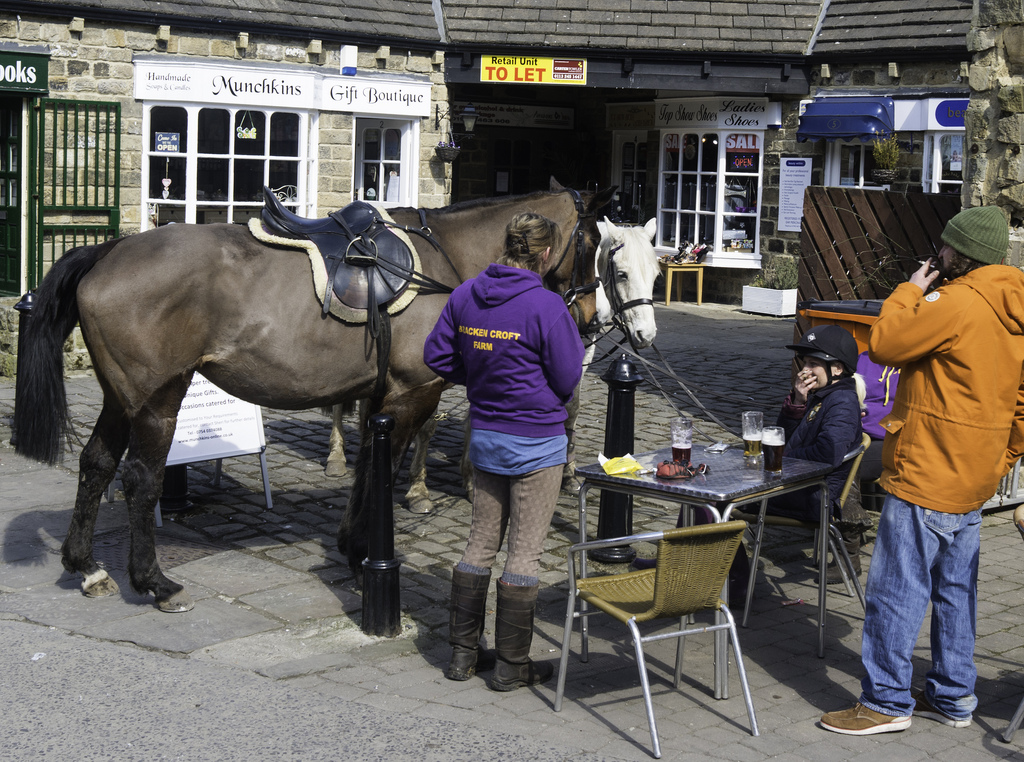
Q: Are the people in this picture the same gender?
A: No, they are both male and female.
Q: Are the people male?
A: No, they are both male and female.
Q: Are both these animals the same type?
A: Yes, all the animals are horses.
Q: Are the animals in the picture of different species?
A: No, all the animals are horses.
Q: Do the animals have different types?
A: No, all the animals are horses.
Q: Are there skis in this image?
A: No, there are no skis.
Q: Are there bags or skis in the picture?
A: No, there are no skis or bags.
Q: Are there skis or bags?
A: No, there are no skis or bags.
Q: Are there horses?
A: Yes, there is a horse.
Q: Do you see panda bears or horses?
A: Yes, there is a horse.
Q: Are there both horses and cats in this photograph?
A: No, there is a horse but no cats.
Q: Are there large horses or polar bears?
A: Yes, there is a large horse.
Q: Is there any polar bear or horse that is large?
A: Yes, the horse is large.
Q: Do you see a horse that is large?
A: Yes, there is a large horse.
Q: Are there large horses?
A: Yes, there is a large horse.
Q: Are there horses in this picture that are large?
A: Yes, there is a horse that is large.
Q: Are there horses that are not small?
A: Yes, there is a large horse.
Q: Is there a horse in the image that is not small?
A: Yes, there is a large horse.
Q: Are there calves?
A: No, there are no calves.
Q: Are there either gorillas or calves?
A: No, there are no calves or gorillas.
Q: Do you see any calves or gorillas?
A: No, there are no calves or gorillas.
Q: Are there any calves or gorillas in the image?
A: No, there are no calves or gorillas.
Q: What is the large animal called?
A: The animal is a horse.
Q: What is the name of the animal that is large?
A: The animal is a horse.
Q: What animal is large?
A: The animal is a horse.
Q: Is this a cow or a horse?
A: This is a horse.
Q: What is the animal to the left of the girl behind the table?
A: The animal is a horse.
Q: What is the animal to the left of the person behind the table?
A: The animal is a horse.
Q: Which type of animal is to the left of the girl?
A: The animal is a horse.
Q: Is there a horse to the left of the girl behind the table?
A: Yes, there is a horse to the left of the girl.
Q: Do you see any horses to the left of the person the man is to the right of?
A: Yes, there is a horse to the left of the girl.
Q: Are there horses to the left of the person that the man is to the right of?
A: Yes, there is a horse to the left of the girl.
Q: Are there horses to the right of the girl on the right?
A: No, the horse is to the left of the girl.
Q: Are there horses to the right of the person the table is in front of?
A: No, the horse is to the left of the girl.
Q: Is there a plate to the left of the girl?
A: No, there is a horse to the left of the girl.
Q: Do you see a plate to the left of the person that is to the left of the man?
A: No, there is a horse to the left of the girl.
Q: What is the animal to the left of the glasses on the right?
A: The animal is a horse.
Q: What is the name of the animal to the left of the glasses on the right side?
A: The animal is a horse.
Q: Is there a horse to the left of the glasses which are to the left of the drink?
A: Yes, there is a horse to the left of the glasses.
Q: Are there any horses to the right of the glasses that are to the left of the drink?
A: No, the horse is to the left of the glasses.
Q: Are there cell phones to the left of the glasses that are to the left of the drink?
A: No, there is a horse to the left of the glasses.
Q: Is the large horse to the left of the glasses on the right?
A: Yes, the horse is to the left of the glasses.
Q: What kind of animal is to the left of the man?
A: The animal is a horse.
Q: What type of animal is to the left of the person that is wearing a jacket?
A: The animal is a horse.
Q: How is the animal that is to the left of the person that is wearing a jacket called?
A: The animal is a horse.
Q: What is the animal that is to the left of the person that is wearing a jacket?
A: The animal is a horse.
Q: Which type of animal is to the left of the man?
A: The animal is a horse.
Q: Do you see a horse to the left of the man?
A: Yes, there is a horse to the left of the man.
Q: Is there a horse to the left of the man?
A: Yes, there is a horse to the left of the man.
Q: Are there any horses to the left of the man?
A: Yes, there is a horse to the left of the man.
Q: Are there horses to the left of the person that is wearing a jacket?
A: Yes, there is a horse to the left of the man.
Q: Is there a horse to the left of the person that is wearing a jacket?
A: Yes, there is a horse to the left of the man.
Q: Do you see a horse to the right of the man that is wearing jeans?
A: No, the horse is to the left of the man.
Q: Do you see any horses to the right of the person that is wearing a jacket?
A: No, the horse is to the left of the man.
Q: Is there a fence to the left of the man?
A: No, there is a horse to the left of the man.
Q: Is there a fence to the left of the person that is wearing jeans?
A: No, there is a horse to the left of the man.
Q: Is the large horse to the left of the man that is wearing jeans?
A: Yes, the horse is to the left of the man.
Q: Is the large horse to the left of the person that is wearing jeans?
A: Yes, the horse is to the left of the man.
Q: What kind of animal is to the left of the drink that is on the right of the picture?
A: The animal is a horse.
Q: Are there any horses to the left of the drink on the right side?
A: Yes, there is a horse to the left of the drink.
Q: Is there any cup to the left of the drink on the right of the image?
A: No, there is a horse to the left of the drink.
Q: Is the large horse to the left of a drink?
A: Yes, the horse is to the left of a drink.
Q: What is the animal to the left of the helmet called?
A: The animal is a horse.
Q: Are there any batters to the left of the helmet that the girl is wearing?
A: No, there is a horse to the left of the helmet.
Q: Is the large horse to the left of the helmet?
A: Yes, the horse is to the left of the helmet.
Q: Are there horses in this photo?
A: Yes, there is a horse.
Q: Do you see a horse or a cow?
A: Yes, there is a horse.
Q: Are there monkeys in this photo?
A: No, there are no monkeys.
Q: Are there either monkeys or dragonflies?
A: No, there are no monkeys or dragonflies.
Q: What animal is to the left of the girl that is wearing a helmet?
A: The animal is a horse.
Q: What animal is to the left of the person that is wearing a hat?
A: The animal is a horse.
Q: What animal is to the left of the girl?
A: The animal is a horse.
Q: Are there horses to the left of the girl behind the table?
A: Yes, there is a horse to the left of the girl.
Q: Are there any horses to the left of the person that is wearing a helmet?
A: Yes, there is a horse to the left of the girl.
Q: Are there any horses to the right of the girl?
A: No, the horse is to the left of the girl.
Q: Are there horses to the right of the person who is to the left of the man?
A: No, the horse is to the left of the girl.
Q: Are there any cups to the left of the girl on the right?
A: No, there is a horse to the left of the girl.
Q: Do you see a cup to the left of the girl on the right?
A: No, there is a horse to the left of the girl.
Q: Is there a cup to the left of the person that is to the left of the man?
A: No, there is a horse to the left of the girl.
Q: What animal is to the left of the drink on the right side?
A: The animal is a horse.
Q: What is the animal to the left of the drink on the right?
A: The animal is a horse.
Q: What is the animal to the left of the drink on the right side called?
A: The animal is a horse.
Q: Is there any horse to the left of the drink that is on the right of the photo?
A: Yes, there is a horse to the left of the drink.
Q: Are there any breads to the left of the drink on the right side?
A: No, there is a horse to the left of the drink.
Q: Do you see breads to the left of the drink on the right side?
A: No, there is a horse to the left of the drink.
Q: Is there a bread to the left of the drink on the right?
A: No, there is a horse to the left of the drink.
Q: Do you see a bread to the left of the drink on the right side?
A: No, there is a horse to the left of the drink.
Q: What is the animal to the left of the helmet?
A: The animal is a horse.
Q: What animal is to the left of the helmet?
A: The animal is a horse.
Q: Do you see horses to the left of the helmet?
A: Yes, there is a horse to the left of the helmet.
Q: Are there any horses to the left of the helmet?
A: Yes, there is a horse to the left of the helmet.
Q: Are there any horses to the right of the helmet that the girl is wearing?
A: No, the horse is to the left of the helmet.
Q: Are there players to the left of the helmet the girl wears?
A: No, there is a horse to the left of the helmet.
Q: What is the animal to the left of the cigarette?
A: The animal is a horse.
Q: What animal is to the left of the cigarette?
A: The animal is a horse.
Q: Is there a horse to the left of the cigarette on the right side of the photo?
A: Yes, there is a horse to the left of the cigarette.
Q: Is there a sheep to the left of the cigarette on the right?
A: No, there is a horse to the left of the cigarette.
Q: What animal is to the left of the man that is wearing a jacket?
A: The animal is a horse.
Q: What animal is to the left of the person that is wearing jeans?
A: The animal is a horse.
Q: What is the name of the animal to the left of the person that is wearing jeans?
A: The animal is a horse.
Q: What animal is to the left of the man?
A: The animal is a horse.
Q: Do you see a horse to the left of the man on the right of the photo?
A: Yes, there is a horse to the left of the man.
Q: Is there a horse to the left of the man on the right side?
A: Yes, there is a horse to the left of the man.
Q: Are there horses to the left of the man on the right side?
A: Yes, there is a horse to the left of the man.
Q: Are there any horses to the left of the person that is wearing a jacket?
A: Yes, there is a horse to the left of the man.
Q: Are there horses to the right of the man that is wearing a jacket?
A: No, the horse is to the left of the man.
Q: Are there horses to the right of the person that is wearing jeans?
A: No, the horse is to the left of the man.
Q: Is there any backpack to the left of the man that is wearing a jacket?
A: No, there is a horse to the left of the man.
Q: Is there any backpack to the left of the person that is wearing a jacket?
A: No, there is a horse to the left of the man.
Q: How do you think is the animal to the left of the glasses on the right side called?
A: The animal is a horse.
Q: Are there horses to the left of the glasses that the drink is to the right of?
A: Yes, there is a horse to the left of the glasses.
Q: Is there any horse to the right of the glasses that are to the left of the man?
A: No, the horse is to the left of the glasses.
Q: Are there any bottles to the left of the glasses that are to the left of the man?
A: No, there is a horse to the left of the glasses.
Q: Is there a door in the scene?
A: Yes, there is a door.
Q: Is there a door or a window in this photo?
A: Yes, there is a door.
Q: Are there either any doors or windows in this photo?
A: Yes, there is a door.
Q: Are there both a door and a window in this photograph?
A: Yes, there are both a door and a window.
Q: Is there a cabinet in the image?
A: No, there are no cabinets.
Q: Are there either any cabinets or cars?
A: No, there are no cabinets or cars.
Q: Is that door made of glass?
A: No, the door is made of iron.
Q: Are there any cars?
A: No, there are no cars.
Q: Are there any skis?
A: No, there are no skis.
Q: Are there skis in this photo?
A: No, there are no skis.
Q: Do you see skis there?
A: No, there are no skis.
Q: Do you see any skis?
A: No, there are no skis.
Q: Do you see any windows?
A: Yes, there is a window.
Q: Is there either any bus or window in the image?
A: Yes, there is a window.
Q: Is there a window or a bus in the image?
A: Yes, there is a window.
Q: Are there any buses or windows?
A: Yes, there is a window.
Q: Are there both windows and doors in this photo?
A: Yes, there are both a window and a door.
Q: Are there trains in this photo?
A: No, there are no trains.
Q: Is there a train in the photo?
A: No, there are no trains.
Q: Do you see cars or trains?
A: No, there are no trains or cars.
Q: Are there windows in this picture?
A: Yes, there is a window.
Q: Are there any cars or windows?
A: Yes, there is a window.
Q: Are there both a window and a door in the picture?
A: Yes, there are both a window and a door.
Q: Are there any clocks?
A: No, there are no clocks.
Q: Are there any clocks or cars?
A: No, there are no clocks or cars.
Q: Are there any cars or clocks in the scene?
A: No, there are no clocks or cars.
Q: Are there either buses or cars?
A: No, there are no cars or buses.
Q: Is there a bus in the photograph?
A: No, there are no buses.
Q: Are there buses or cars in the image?
A: No, there are no buses or cars.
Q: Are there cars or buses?
A: No, there are no buses or cars.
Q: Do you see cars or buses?
A: No, there are no buses or cars.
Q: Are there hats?
A: Yes, there is a hat.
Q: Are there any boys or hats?
A: Yes, there is a hat.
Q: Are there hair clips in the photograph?
A: No, there are no hair clips.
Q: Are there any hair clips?
A: No, there are no hair clips.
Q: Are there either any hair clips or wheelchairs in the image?
A: No, there are no hair clips or wheelchairs.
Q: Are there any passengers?
A: No, there are no passengers.